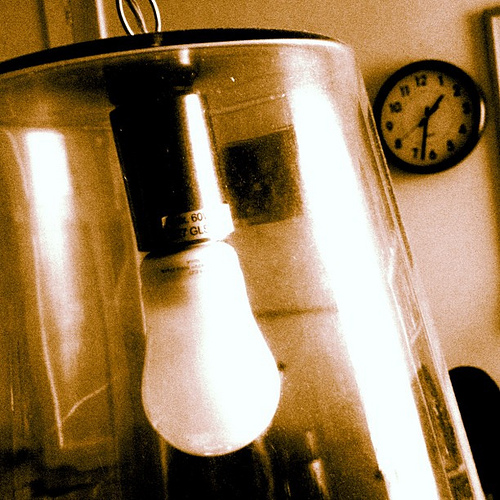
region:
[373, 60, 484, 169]
a clock on the wall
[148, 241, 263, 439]
a light bulb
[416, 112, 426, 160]
the minute hand of the clock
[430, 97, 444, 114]
the hour hand on the clock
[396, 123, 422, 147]
the second hand on the clock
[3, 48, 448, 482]
a metal vase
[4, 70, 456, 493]
a light bulb in a glass container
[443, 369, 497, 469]
a black object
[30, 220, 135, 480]
a door in the background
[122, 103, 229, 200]
the top of the light bulb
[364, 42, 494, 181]
The clock is round.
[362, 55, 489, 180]
The clock frame is black.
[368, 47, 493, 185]
The clock face is white.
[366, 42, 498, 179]
The hour and minute hand on the clock is black.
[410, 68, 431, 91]
The number is black.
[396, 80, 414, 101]
The number is black.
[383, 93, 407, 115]
The number is black.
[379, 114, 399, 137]
The number is black.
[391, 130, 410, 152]
The number is black.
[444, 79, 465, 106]
The number is black.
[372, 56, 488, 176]
A clock on the wall.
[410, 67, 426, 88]
The number twelve on a clock.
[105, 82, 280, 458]
A white light bulb.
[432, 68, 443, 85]
The number one on a clock.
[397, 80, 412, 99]
The number eleven on a clock.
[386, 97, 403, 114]
The number ten on a clock.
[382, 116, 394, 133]
The number nine on a clock.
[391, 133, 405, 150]
The number eight on a clock.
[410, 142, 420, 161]
The number seven on a clock.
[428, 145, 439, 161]
The number six on a clock.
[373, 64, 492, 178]
clock on the wall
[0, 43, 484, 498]
light bulb in a clear container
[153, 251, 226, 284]
label on the light bulb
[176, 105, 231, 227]
light glare on the bulb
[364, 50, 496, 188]
clock indicating it's a little after 1:30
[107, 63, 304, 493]
light bulb hanging upside down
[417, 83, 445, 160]
two black clock hands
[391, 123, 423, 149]
skinny hand that indicates the seconds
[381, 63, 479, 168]
numbers around the circumference of the clock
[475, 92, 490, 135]
light glare on the clock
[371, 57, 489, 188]
clock indicating it's a little past 1:30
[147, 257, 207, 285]
label on the bulb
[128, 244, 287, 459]
white lightbulb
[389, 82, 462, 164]
two black clock hands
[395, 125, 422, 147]
skinny hand for the seconds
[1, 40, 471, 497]
bulb in a clear container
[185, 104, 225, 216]
light shining on the bulb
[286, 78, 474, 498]
large light glare